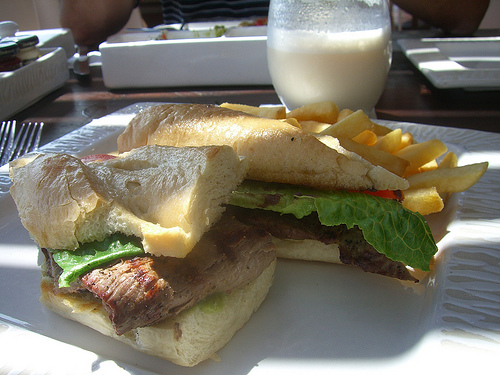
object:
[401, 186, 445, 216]
fries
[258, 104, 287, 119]
fries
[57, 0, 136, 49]
elbow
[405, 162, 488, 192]
french fries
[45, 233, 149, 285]
lettuce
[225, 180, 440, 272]
lettuce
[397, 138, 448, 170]
frenchfries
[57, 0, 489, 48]
person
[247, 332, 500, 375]
sunlight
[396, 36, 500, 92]
an empty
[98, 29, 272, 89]
tray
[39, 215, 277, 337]
meat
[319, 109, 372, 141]
fry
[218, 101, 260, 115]
fry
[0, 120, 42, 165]
fork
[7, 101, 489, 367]
food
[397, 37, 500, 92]
tray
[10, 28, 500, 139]
table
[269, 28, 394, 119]
drink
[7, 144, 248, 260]
roll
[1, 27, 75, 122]
white plate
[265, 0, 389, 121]
clear glass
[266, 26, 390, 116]
milk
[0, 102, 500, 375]
plate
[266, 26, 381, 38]
froth